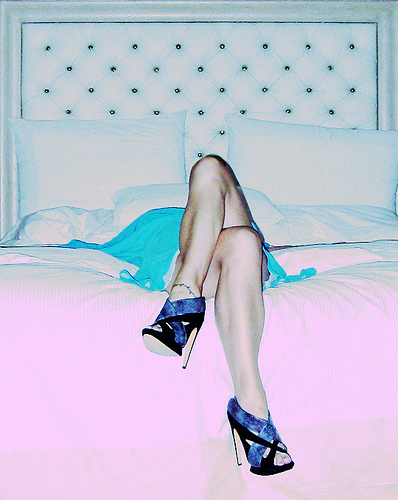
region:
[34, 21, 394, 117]
white colored headboard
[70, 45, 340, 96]
nail head studs on bed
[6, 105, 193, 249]
white pillow on headboard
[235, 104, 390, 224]
slightly slanted white pillow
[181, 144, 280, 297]
knee caps of woman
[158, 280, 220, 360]
blue and black tye dye shoes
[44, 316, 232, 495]
pink colored bed cover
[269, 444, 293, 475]
woman's bare toes out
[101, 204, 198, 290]
blue dress on woman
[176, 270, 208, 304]
ankle tattoo on leg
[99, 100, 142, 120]
small black spot on bed head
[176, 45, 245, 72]
tiny lines on bed head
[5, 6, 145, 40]
solid black lines on the bed head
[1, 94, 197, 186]
blue pillow on bed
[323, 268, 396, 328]
lines in the pink sheet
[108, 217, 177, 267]
person wearing blue dress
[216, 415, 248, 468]
long heel on shoes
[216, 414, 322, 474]
black leather on high heel shoe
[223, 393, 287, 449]
blue felt on shoe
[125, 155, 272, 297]
person's leg crossed on bed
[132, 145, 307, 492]
A pair of sexy legs on a bed.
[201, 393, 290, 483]
A pair of blue shoes on a sexy foot.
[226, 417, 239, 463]
The heel of a high heeled shoe.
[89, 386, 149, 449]
A pink bed spread.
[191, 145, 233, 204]
A knee of a sexy girl.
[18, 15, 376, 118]
The padded head bored on a bead.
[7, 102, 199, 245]
A white pillow on a head board.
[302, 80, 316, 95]
A button on a head board.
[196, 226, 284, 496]
A sexy leg wearing a high heel.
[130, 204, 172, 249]
The right breast of a woman.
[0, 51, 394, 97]
A cushioned head board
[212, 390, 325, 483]
A blue ribbon with black high heels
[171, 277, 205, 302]
A tattoo around the ankle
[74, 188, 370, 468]
A woman laying the bed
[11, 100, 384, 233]
Pillows at the top of the bed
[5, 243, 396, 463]
A striped bed spread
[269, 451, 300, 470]
Painted toe nails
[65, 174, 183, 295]
An aqua colored dress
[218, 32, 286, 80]
Black beads in the head board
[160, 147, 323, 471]
The woman's long legs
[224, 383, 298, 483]
a blue and black high heel shoe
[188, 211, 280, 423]
the leg of a woman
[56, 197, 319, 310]
a bright blue dress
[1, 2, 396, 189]
a white head board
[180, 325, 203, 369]
the heel of a shoe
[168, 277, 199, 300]
a small anklet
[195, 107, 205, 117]
a button on the head board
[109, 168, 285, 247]
a white pillow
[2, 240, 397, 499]
a white bed spread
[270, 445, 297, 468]
the toes of the woman